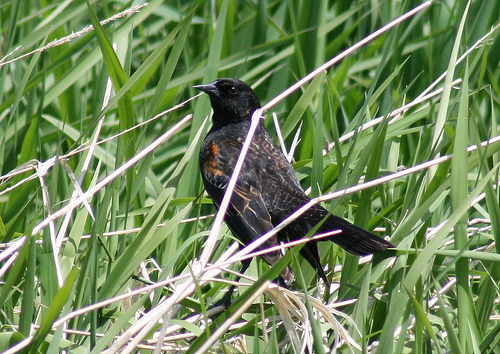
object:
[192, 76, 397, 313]
bird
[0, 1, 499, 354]
grass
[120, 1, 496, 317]
branches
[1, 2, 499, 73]
air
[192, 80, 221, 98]
beak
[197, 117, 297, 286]
feathers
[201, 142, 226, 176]
orange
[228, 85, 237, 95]
eyes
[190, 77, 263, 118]
head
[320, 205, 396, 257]
tail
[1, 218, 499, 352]
ground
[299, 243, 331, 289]
feather